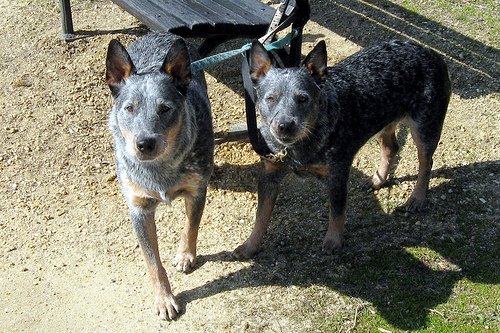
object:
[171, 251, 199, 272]
foot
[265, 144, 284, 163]
clip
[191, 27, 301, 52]
metal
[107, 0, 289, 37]
wood bench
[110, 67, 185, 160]
face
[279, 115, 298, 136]
dognose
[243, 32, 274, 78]
ear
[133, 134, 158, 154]
nose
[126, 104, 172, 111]
dogs eyes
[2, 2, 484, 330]
dirt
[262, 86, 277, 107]
eye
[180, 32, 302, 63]
leash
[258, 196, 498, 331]
grassy area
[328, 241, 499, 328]
right corner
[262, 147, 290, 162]
hook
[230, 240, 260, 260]
paw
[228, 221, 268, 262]
foot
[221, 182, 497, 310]
shadow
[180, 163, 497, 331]
shadow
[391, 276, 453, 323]
grass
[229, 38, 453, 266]
dog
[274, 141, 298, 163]
collar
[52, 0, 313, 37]
bench